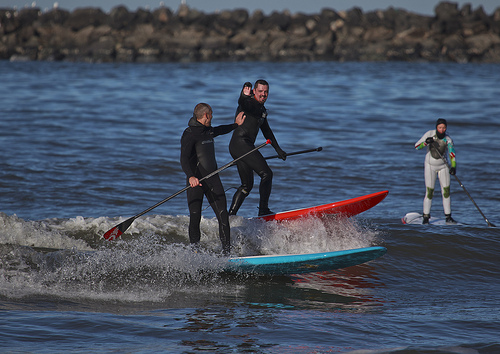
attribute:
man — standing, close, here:
[227, 77, 301, 215]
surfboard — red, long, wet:
[300, 181, 389, 217]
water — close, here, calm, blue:
[26, 81, 117, 155]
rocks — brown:
[205, 7, 290, 47]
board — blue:
[208, 245, 396, 275]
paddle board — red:
[252, 190, 383, 225]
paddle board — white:
[395, 209, 493, 230]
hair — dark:
[182, 96, 211, 121]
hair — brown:
[252, 71, 268, 89]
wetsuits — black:
[228, 111, 295, 221]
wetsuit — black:
[172, 124, 239, 258]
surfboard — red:
[273, 180, 393, 225]